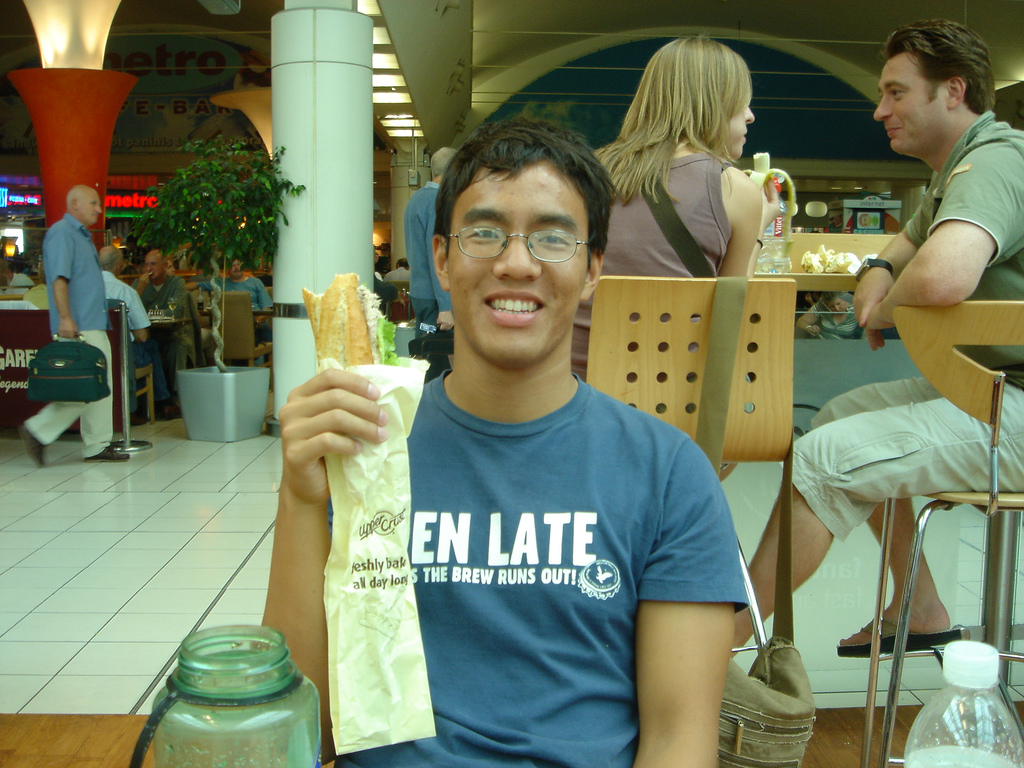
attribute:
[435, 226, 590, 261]
glasses — wire framed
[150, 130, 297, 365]
tree — indoor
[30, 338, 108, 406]
bag — small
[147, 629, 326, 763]
jar — green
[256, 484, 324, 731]
arm — glass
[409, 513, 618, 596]
writing — white